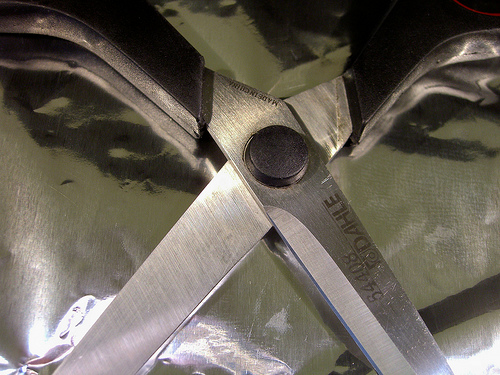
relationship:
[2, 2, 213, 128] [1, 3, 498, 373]
handle of scissor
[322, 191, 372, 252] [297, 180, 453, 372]
dahle on blade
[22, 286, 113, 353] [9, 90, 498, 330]
light shining on tin foil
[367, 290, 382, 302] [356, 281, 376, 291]
number on number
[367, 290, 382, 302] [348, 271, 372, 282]
number on number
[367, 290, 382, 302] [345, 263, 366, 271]
number on number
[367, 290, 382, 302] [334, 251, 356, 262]
number on number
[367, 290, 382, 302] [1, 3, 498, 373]
number on scissor